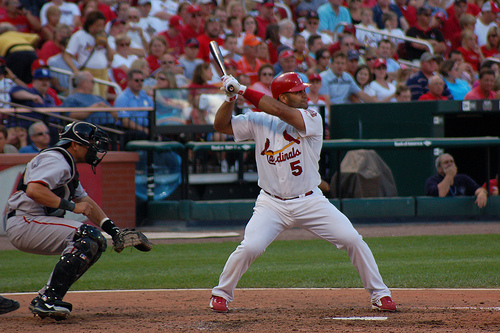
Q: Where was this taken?
A: Baseball field.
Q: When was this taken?
A: During a baseball game.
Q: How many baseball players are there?
A: 2.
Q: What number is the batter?
A: 5.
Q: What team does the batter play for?
A: Cardinals.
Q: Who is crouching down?
A: Catcher.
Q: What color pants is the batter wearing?
A: White.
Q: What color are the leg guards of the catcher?
A: Black.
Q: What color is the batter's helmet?
A: Red.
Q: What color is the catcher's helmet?
A: Black.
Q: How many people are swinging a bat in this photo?
A: One.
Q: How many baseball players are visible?
A: Two.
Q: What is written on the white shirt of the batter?
A: Cardinals.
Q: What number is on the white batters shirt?
A: 5.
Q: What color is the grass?
A: Green.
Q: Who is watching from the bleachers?
A: Spectators.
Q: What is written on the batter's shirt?
A: Cardinals.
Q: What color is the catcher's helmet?
A: Black.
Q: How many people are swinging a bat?
A: One.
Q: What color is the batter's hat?
A: Red.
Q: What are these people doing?
A: Playing baseball.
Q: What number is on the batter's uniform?
A: 5.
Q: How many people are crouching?
A: One.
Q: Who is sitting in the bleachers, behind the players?
A: Baseball fan/viewers.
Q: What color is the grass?
A: Green.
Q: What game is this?
A: Baseball.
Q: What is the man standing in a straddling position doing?
A: Getting ready to bat.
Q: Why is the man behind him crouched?
A: He is ready to catch the ball, in case the batter misses it.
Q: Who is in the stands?
A: Spectators.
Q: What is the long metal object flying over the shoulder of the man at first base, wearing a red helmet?
A: A baseball bat.